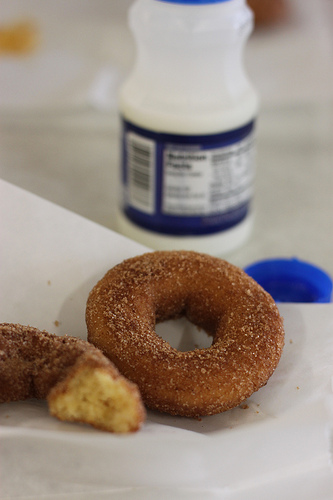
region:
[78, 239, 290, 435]
A brown dount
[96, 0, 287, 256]
A bottle of milk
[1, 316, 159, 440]
A half eaten donut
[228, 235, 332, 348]
Blue milk bottle cap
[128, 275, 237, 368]
A dount hole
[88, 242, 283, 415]
A donut with lite sprinkles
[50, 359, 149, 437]
A bitten into donut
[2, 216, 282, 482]
Donuts sitting on a napkin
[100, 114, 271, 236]
Nutrition facts on a milk bottle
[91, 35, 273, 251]
A milk bottle with some milk left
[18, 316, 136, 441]
A half eaten doughnut.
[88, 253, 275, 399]
A whole doughnut.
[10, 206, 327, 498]
The doughnuts are on a white box.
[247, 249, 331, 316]
The cap to the milk is on the counter.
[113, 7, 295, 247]
A small jug of milk is on the counter.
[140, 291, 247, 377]
There is a hole in the doughnut.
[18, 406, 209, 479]
The doughnuts are on a sheet in the box.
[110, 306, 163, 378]
The doughnut is brown.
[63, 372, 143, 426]
The inside of this doughnut is yellow.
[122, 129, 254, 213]
There is a blue label on the jug.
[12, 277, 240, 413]
Two donuts are seen.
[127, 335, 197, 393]
Donuts are brown color.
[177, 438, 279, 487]
Tissue paper is white color.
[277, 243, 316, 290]
Cap is blue color.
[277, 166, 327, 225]
Table is white color.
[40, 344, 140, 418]
Donuts are half eaten.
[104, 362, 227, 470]
Donuts in the paper.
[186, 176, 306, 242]
Bottle is in table.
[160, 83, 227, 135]
Bottle is white color.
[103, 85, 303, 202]
One bottle is seen.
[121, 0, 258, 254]
the plastic bottle has a blue label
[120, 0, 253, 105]
the plastic bottle has a blue top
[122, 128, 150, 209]
the bottle has a price code on the outside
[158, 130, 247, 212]
the ingredients in the bottle are listed on the its side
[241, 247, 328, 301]
a blue bottle top is on the table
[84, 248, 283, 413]
a sugar doughnut is on a waxpaper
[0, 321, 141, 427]
a half eaten doughnut is on wax paper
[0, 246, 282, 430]
two doughnuts are sitting on wax paper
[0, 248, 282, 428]
the doughnuts are full of brown sugar crystals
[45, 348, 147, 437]
the inside of the doughnut is yellow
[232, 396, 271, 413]
crumbs on white surface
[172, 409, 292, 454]
shadow of doughnut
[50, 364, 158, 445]
half eaten doughnut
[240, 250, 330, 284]
blue edge of object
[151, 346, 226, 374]
sugar on brown donut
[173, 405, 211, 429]
brown crust on doughnut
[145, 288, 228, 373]
large hole in cinnamon doughnut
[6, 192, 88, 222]
edge of white surface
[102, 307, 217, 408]
cinnamon sugar on doughnut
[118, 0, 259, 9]
top of large white bottle